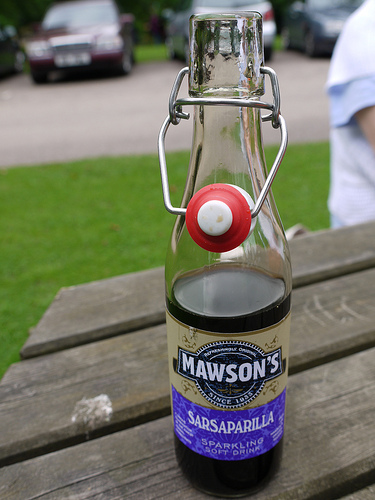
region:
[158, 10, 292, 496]
the clear bottle on the table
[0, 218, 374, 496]
the wooden table under the clear glass bottle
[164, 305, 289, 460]
the label on the clear glass bottle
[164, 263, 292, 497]
the liquid in the clear glass bottle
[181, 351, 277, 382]
the word "MAWSON'S" on the label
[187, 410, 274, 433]
the word "SARSAPARILLA" on the label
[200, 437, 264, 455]
the words "SPARKLING SOFT DRINK" on the label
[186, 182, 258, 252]
the red and white bottle cover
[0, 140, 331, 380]
the green grass on the ground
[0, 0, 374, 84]
the cars parked in the background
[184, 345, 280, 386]
the word is white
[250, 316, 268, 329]
the liquid is black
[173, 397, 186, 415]
the bottom part of the lable is purple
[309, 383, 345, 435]
the table is weathered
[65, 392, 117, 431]
a bird pooped on the table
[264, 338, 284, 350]
the top part of the lable is tan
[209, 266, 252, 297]
the bottle is glass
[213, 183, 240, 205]
the mouth cover is red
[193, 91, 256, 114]
the mouth holder is silver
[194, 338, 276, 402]
the middle of the lable is blue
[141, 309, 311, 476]
mawson's sarsaparilla label on bottle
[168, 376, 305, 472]
white printing on blue label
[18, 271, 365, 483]
wooden slats on picnic table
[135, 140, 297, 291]
red and white top of bottle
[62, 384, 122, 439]
white bird poop on wooden table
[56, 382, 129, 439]
white bird dropping on picnic table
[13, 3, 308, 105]
cars parked in park parking lot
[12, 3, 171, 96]
dark red car parked in lot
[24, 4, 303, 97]
cars parked in lot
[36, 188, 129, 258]
green grass in park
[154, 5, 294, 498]
Half-empty bottle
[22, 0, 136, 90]
Maroon car out of focus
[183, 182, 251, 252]
Red bottle stopper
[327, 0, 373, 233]
White shirt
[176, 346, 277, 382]
Brand name of beverage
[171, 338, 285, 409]
Logo on beverage bottle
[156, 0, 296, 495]
Bottle is made of glass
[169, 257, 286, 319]
Liquid refracted in the glass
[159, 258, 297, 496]
Dark, purple liquid in bottle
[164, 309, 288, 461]
Yellow and Purple drink label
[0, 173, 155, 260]
Green grass in the background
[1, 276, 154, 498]
A brown, wooden table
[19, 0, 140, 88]
An out of focus car in the background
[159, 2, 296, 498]
A bottle of Mawson's Sasaparilla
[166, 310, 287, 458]
A label on the bottle of Mawson's sarsaparilla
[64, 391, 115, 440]
A white stain on the wooden table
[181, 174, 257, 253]
A red and white bottle cork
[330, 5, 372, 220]
An out of focus person wearing a t-shirt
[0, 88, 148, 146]
Gray pavement in a parking lot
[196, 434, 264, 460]
A sparkling soft drink label